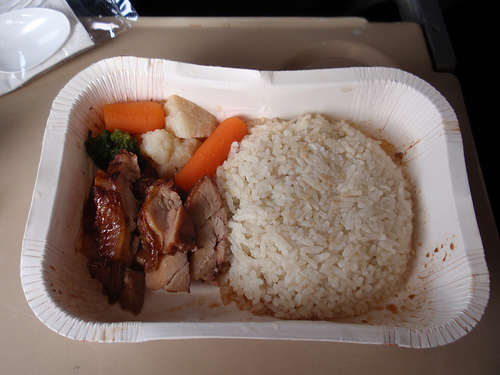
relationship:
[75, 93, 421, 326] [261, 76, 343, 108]
food in tray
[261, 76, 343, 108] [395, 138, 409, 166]
tray has sauce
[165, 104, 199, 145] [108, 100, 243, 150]
cauliflower between two carrots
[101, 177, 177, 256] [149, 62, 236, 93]
beef in a container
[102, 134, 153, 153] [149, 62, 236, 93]
veggie in a container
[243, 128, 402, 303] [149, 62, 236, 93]
rice in a container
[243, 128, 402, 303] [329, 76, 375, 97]
rice on a plate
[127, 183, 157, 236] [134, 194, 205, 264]
pieces of meat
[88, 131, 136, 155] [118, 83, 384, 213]
broccoli next to meal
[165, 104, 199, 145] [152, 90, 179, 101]
cauliflower in corner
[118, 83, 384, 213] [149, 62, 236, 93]
meal in container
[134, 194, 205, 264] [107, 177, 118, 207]
meat has skin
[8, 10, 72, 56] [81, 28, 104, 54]
spoon in plastic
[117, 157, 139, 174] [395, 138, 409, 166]
chicken with sauce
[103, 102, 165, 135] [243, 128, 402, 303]
baby carrot beside rice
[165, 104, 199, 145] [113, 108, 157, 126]
cauliflower beside baby carrot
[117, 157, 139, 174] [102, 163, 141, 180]
chicken has glaze